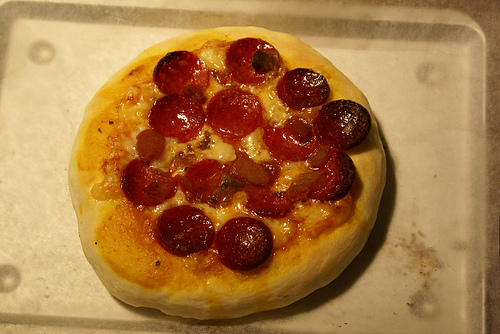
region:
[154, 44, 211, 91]
Red pepperoni on pizza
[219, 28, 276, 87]
Red pepperoni on pizza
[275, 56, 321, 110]
Red pepperoni on pizza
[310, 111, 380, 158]
Red pepperoni on pizza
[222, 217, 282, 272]
Red pepperoni on pizza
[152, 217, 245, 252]
Red pepperoni on pizza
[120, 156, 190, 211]
Red pepperoni on pizza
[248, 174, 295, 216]
Red pepperoni on pizza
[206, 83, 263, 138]
Red pepperoni on pizza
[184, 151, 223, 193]
Red pepperoni on pizza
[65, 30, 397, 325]
a pizza on a tray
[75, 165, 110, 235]
the crust of a pizza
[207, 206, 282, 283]
a slice of pepperoni on a pizza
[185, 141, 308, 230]
the toppings of a pizza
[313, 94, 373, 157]
an extra crispy slice of pepperoni on a pizza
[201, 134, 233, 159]
the melted cheese on top of a pizza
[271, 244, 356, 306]
the crust of a pizza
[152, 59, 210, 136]
slices of pepperonis on a pizza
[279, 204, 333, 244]
melted cheese on top of a pizza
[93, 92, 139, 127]
the crust of a pizza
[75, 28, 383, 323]
Pepperoni pizza on the tray.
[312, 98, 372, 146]
Burnt pepperoni on the pizza.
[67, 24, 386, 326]
Light tan crust on the pizza.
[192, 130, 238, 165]
Melted cheese on the pizza.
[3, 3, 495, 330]
Gray metal pan under the pizza.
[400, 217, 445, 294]
Stain on the oven glass.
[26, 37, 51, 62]
Raised indentation in the pizza pan.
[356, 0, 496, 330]
Grey surface under pizza pan.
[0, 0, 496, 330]
Glass oven door in the forefront.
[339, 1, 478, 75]
Wet steam on the oven glass.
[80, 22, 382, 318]
food on a pan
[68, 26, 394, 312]
the food is specifically pizza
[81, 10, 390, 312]
the pizza is pepperoni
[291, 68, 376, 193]
the pepperoni has burnt parts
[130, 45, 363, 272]
the pepperoni is red in color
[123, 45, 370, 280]
cheese is on the pizza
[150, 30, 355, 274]
the cheese is nicely melted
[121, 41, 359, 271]
the cheese is a pretty yellow color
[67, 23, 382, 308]
the crust of the pizza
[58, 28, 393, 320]
the crust is tan in color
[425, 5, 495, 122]
corner of metal pan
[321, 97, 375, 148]
burnt pepperoni on the pizza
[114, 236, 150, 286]
melted cheese on the crust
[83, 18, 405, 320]
pizza on the pan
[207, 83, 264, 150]
pepperoni in middle of melted cheese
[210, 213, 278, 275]
pepperoni with burnt edge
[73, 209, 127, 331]
crust of pizza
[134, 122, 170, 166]
browned onion on pizza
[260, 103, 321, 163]
cheese covering the pepperoni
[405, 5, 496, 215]
metal baking pan